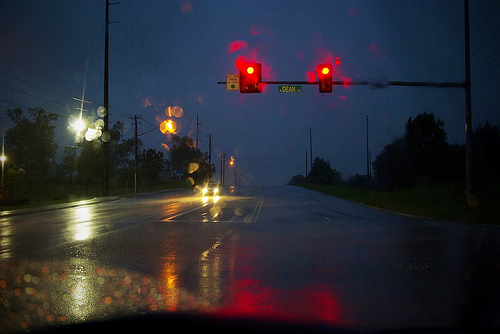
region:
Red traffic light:
[236, 51, 270, 100]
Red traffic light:
[304, 56, 356, 98]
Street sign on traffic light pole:
[274, 79, 310, 98]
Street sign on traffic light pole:
[223, 67, 243, 92]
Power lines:
[65, 0, 245, 196]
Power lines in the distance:
[280, 102, 392, 198]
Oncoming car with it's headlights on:
[186, 171, 238, 207]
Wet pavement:
[0, 170, 481, 332]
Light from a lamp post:
[53, 82, 110, 196]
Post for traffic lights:
[394, 0, 486, 227]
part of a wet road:
[290, 241, 375, 280]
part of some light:
[202, 182, 227, 204]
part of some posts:
[216, 157, 231, 187]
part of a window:
[113, 205, 223, 304]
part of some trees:
[132, 142, 179, 189]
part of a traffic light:
[227, 47, 291, 124]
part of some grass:
[420, 187, 452, 212]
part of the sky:
[235, 71, 292, 163]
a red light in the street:
[238, 56, 262, 79]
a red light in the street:
[313, 60, 338, 83]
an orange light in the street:
[156, 104, 185, 143]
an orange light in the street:
[226, 155, 239, 172]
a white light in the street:
[62, 102, 93, 138]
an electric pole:
[101, 5, 108, 180]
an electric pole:
[457, 5, 478, 205]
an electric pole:
[357, 113, 371, 177]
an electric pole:
[306, 127, 316, 169]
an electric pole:
[216, 151, 226, 188]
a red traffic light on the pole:
[238, 62, 256, 75]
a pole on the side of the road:
[456, 3, 486, 208]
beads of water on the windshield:
[66, 39, 363, 187]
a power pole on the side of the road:
[97, 5, 125, 193]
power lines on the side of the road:
[101, 2, 243, 183]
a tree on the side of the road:
[373, 106, 458, 190]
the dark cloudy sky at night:
[2, 2, 496, 175]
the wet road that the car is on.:
[2, 183, 497, 328]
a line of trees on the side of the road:
[11, 107, 194, 199]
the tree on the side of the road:
[289, 159, 343, 186]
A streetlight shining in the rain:
[61, 100, 116, 147]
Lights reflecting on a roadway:
[105, 225, 340, 315]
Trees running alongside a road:
[0, 115, 215, 210]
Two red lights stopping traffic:
[225, 55, 335, 95]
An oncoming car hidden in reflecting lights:
[192, 175, 232, 200]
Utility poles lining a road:
[185, 110, 232, 165]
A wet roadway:
[235, 225, 441, 282]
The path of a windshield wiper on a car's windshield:
[40, 210, 242, 330]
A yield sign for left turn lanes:
[217, 67, 249, 97]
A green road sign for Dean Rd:
[274, 75, 313, 100]